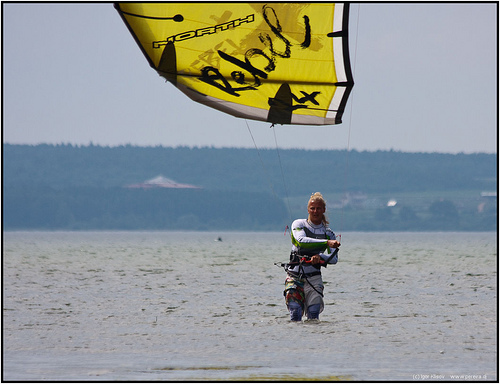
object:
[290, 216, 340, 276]
shirt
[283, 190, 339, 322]
kite flier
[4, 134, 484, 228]
hill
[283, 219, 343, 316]
wet suit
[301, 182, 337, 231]
hair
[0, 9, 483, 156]
sky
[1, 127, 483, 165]
horizon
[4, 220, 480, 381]
water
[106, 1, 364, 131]
parasail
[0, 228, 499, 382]
beach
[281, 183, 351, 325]
woman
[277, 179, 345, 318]
lady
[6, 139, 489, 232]
trees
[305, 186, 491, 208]
field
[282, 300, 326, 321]
knees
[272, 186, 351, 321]
person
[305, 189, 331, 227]
head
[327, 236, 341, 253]
hand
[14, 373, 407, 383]
beach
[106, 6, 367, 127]
kite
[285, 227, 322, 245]
arm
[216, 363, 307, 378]
white churning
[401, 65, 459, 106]
white clouds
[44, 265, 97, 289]
ripples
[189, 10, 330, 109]
black letters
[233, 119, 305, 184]
lines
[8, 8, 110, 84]
haze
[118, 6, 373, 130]
yellow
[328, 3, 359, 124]
white edge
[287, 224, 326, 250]
white sleeve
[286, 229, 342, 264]
two hands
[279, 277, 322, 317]
two legs